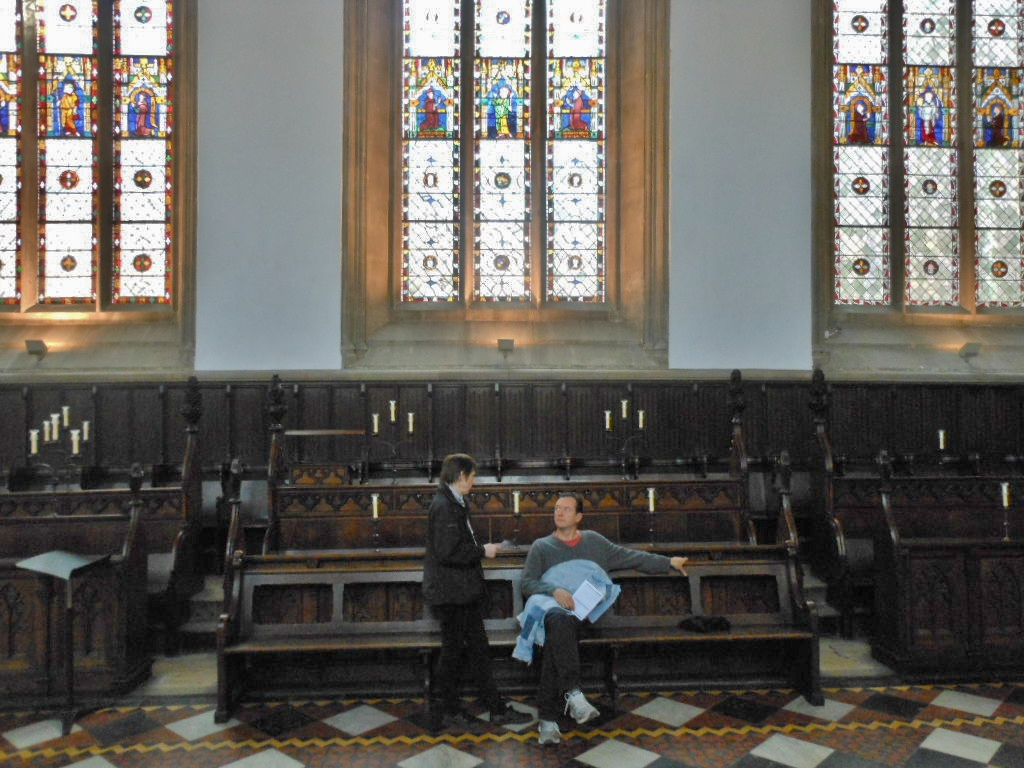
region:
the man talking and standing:
[422, 448, 530, 737]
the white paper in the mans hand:
[563, 575, 606, 621]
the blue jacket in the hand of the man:
[511, 559, 617, 665]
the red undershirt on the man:
[557, 536, 586, 549]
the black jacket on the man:
[424, 482, 488, 619]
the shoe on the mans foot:
[563, 689, 599, 727]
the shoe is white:
[535, 719, 567, 749]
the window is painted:
[403, 5, 609, 307]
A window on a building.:
[549, 144, 601, 287]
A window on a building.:
[471, 131, 523, 284]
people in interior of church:
[5, 1, 1021, 763]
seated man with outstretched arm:
[517, 494, 689, 744]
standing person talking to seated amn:
[419, 452, 683, 734]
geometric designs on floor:
[2, 682, 1020, 766]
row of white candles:
[29, 402, 71, 464]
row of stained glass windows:
[399, 3, 612, 323]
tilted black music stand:
[13, 547, 106, 741]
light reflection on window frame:
[466, 313, 547, 374]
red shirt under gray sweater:
[525, 530, 665, 595]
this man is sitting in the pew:
[510, 490, 695, 753]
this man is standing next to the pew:
[419, 427, 525, 742]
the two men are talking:
[409, 452, 695, 754]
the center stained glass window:
[331, 0, 689, 385]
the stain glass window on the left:
[0, 1, 199, 356]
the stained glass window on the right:
[800, 0, 1013, 387]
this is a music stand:
[11, 538, 120, 760]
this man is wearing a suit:
[413, 449, 518, 741]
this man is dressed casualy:
[508, 484, 696, 754]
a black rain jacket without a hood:
[419, 480, 505, 620]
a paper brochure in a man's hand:
[556, 572, 607, 629]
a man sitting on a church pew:
[527, 483, 695, 747]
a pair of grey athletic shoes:
[520, 688, 609, 765]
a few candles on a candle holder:
[15, 397, 101, 503]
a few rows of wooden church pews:
[10, 388, 1019, 693]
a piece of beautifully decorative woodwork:
[893, 546, 970, 687]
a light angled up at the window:
[474, 319, 529, 371]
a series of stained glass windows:
[378, 0, 650, 358]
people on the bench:
[269, 405, 751, 700]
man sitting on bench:
[462, 429, 707, 753]